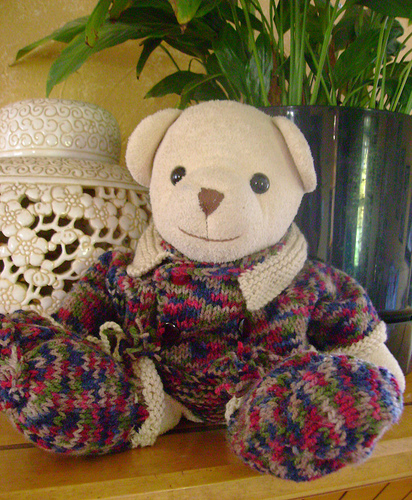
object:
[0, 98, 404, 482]
teddy bear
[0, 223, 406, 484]
outfit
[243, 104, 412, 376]
planter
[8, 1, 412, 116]
plant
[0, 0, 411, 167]
walks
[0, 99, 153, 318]
vase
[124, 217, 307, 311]
collar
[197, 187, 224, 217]
nose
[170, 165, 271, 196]
eyes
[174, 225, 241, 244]
mouth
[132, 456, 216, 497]
fish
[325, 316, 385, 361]
cuff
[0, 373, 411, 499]
table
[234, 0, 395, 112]
stems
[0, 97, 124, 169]
pattern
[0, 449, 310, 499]
lines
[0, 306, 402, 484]
shoes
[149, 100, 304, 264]
face